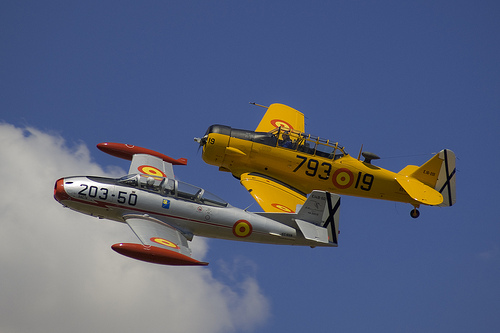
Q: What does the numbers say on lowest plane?
A: 20360.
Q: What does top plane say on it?
A: 79319'.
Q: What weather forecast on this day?
A: Sunny.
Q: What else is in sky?
A: Clouds.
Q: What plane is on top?
A: Yellow.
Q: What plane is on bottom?
A: Red.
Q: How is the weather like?
A: Sunny.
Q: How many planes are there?
A: Two.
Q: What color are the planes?
A: Yellow and Gray.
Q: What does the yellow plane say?
A: 79319.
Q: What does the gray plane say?
A: 20350.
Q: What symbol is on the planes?
A: A target.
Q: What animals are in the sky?
A: None.